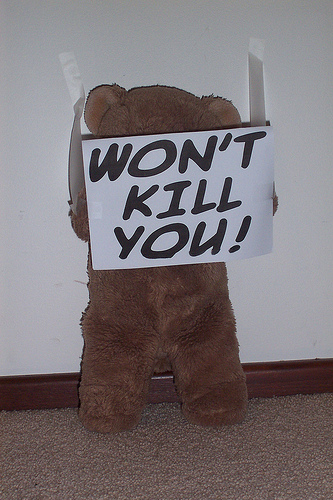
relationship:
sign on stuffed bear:
[79, 125, 282, 272] [68, 82, 249, 433]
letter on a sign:
[108, 217, 146, 266] [80, 127, 272, 271]